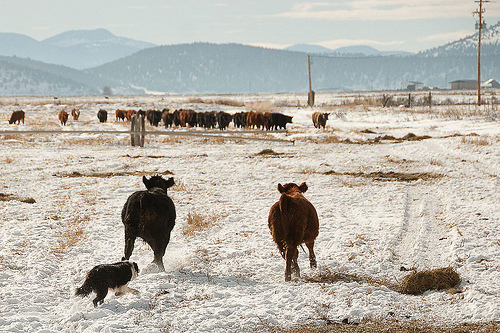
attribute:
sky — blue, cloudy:
[2, 2, 498, 42]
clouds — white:
[257, 0, 494, 21]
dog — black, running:
[76, 256, 141, 308]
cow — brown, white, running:
[269, 181, 318, 282]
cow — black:
[122, 178, 175, 271]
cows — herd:
[10, 107, 330, 133]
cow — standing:
[8, 112, 25, 126]